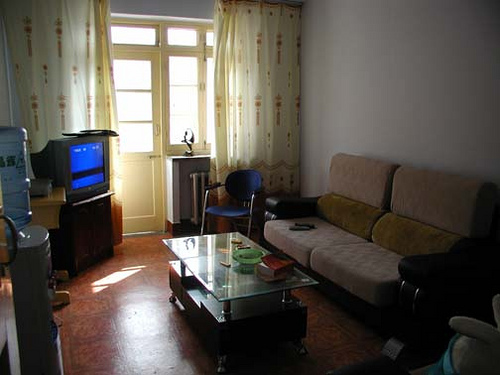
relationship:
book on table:
[257, 253, 296, 277] [163, 226, 322, 367]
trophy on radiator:
[176, 124, 196, 155] [188, 172, 208, 225]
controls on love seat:
[287, 217, 317, 236] [262, 146, 500, 318]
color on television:
[72, 147, 107, 187] [44, 132, 146, 223]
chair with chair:
[192, 153, 284, 250] [200, 170, 263, 239]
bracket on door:
[148, 151, 162, 161] [101, 36, 204, 248]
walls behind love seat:
[301, 5, 494, 212] [262, 146, 500, 318]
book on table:
[252, 250, 295, 279] [163, 226, 322, 367]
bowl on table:
[234, 246, 264, 272] [118, 203, 318, 338]